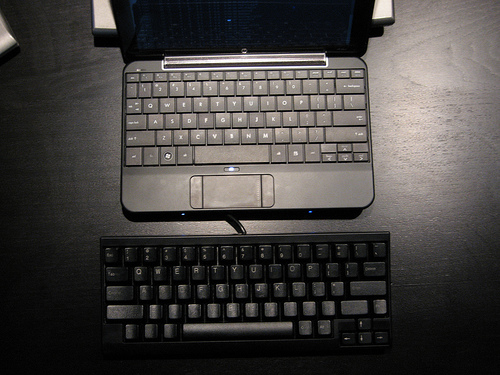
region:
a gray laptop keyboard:
[118, 55, 375, 210]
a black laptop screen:
[108, 0, 368, 59]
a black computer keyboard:
[97, 230, 394, 355]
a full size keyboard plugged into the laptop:
[97, 230, 391, 353]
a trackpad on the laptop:
[188, 173, 275, 207]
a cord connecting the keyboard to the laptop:
[216, 212, 248, 233]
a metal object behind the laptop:
[86, 1, 397, 35]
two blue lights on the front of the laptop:
[176, 210, 315, 217]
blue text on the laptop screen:
[126, 0, 356, 50]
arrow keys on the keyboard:
[338, 316, 385, 344]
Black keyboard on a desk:
[86, 230, 403, 355]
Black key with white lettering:
[132, 264, 146, 280]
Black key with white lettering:
[150, 268, 166, 280]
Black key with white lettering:
[170, 267, 185, 279]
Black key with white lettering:
[187, 263, 204, 281]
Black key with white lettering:
[208, 264, 227, 281]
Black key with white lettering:
[227, 264, 247, 282]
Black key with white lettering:
[247, 263, 267, 280]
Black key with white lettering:
[271, 284, 286, 302]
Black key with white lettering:
[232, 283, 251, 298]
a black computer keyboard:
[46, 136, 481, 374]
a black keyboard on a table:
[60, 171, 457, 374]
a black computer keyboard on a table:
[47, 161, 462, 370]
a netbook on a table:
[87, 9, 497, 300]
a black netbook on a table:
[84, 7, 444, 268]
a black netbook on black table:
[99, 12, 468, 307]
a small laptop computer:
[90, 6, 483, 368]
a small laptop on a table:
[44, 8, 499, 298]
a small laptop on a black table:
[75, 13, 449, 268]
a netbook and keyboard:
[27, 26, 454, 369]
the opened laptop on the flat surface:
[108, 0, 375, 214]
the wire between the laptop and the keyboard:
[223, 211, 247, 233]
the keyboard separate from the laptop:
[97, 232, 388, 347]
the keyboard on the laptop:
[125, 67, 370, 166]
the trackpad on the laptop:
[190, 174, 274, 209]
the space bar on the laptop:
[192, 144, 270, 164]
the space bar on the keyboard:
[181, 320, 293, 334]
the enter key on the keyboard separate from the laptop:
[347, 280, 382, 295]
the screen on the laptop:
[110, 0, 375, 57]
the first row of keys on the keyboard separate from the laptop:
[103, 243, 386, 261]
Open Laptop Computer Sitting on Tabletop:
[2, 1, 498, 227]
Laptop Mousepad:
[189, 173, 275, 212]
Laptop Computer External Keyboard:
[95, 229, 395, 356]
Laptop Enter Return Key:
[331, 108, 368, 127]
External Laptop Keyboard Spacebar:
[184, 320, 294, 335]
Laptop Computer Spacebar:
[194, 144, 269, 164]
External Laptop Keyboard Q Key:
[132, 264, 143, 279]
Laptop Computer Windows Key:
[160, 147, 175, 164]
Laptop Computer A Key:
[148, 114, 162, 129]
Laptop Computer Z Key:
[157, 129, 171, 144]